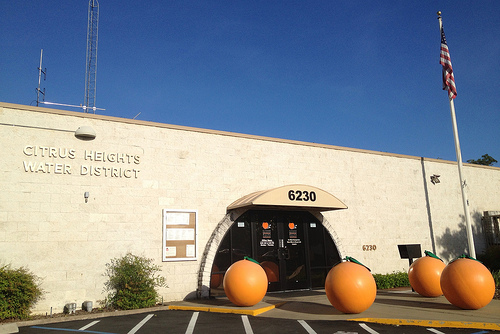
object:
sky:
[176, 29, 296, 103]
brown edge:
[0, 99, 498, 171]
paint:
[364, 314, 500, 332]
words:
[20, 141, 145, 180]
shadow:
[380, 283, 451, 316]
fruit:
[322, 256, 379, 317]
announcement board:
[160, 208, 198, 261]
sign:
[257, 216, 272, 240]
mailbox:
[396, 241, 423, 258]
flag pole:
[430, 10, 477, 263]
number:
[361, 242, 377, 251]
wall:
[1, 105, 500, 315]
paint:
[23, 200, 69, 228]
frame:
[244, 210, 304, 224]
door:
[195, 184, 354, 301]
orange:
[436, 257, 487, 313]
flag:
[435, 23, 457, 100]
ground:
[0, 299, 499, 334]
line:
[186, 309, 199, 334]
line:
[237, 315, 252, 332]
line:
[127, 310, 153, 334]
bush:
[100, 250, 165, 310]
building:
[0, 101, 500, 334]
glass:
[210, 209, 256, 272]